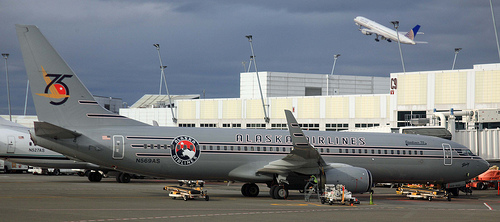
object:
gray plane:
[30, 58, 470, 189]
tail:
[9, 14, 134, 186]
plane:
[346, 7, 434, 52]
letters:
[230, 132, 362, 147]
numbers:
[384, 67, 399, 96]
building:
[240, 69, 499, 123]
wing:
[31, 115, 81, 140]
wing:
[253, 105, 339, 192]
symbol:
[169, 137, 199, 167]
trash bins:
[18, 17, 488, 202]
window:
[245, 122, 267, 129]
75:
[41, 72, 73, 107]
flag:
[99, 132, 113, 142]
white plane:
[351, 12, 428, 47]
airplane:
[32, 63, 469, 186]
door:
[105, 126, 130, 166]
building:
[389, 60, 499, 162]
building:
[238, 67, 390, 99]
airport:
[137, 40, 496, 157]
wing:
[404, 23, 425, 40]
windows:
[140, 143, 152, 149]